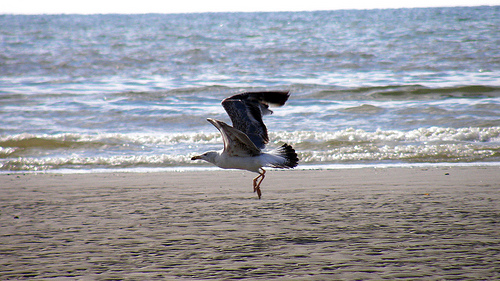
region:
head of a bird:
[189, 150, 220, 164]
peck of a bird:
[183, 147, 202, 176]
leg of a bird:
[240, 165, 285, 202]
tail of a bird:
[265, 131, 311, 168]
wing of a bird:
[209, 108, 268, 153]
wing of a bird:
[211, 73, 288, 133]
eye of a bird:
[200, 147, 210, 156]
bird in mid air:
[177, 65, 334, 217]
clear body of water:
[48, 42, 276, 76]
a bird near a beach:
[163, 51, 340, 215]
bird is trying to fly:
[171, 88, 307, 213]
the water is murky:
[46, 53, 164, 147]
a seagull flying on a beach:
[181, 81, 322, 203]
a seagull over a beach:
[176, 77, 301, 199]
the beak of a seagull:
[188, 152, 202, 162]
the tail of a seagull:
[266, 143, 305, 171]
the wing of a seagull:
[205, 114, 262, 162]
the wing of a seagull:
[220, 90, 293, 143]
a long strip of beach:
[0, 155, 499, 278]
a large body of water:
[0, 2, 499, 170]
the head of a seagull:
[190, 151, 216, 164]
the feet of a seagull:
[249, 171, 273, 201]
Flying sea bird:
[190, 88, 300, 199]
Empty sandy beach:
[0, 160, 495, 276]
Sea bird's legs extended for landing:
[250, 165, 265, 197]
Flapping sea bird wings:
[210, 90, 290, 152]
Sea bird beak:
[187, 150, 199, 165]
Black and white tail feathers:
[266, 141, 296, 167]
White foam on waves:
[300, 121, 495, 161]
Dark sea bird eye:
[202, 150, 207, 156]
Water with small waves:
[0, 15, 495, 170]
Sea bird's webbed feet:
[252, 176, 263, 200]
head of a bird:
[188, 142, 228, 165]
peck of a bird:
[182, 151, 211, 165]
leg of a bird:
[237, 174, 276, 201]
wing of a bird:
[190, 112, 259, 163]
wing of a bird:
[225, 78, 288, 118]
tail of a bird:
[259, 125, 304, 169]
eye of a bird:
[199, 148, 216, 159]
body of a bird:
[205, 139, 300, 189]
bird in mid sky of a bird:
[159, 72, 331, 204]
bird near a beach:
[151, 50, 365, 213]